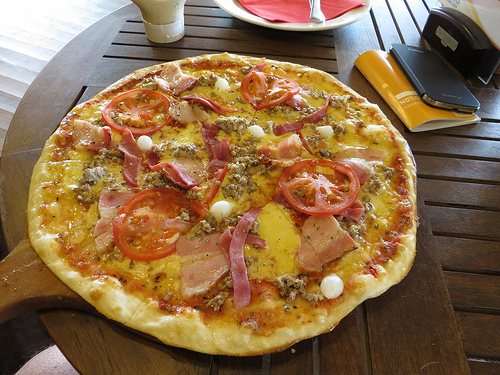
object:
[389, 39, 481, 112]
cellphone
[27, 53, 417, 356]
pizza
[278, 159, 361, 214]
tomato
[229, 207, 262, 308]
ham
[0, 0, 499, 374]
table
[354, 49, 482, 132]
book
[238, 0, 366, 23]
napkin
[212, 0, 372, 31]
plate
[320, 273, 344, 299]
ball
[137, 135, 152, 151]
ball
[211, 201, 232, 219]
ball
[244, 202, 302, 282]
cheese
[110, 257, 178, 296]
cheese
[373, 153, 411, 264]
sauce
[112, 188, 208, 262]
tomato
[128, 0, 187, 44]
cup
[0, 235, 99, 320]
board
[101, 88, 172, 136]
tomato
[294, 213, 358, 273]
meat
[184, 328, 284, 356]
crust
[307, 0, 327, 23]
silverware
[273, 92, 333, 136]
bacon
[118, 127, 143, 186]
strip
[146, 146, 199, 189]
strip